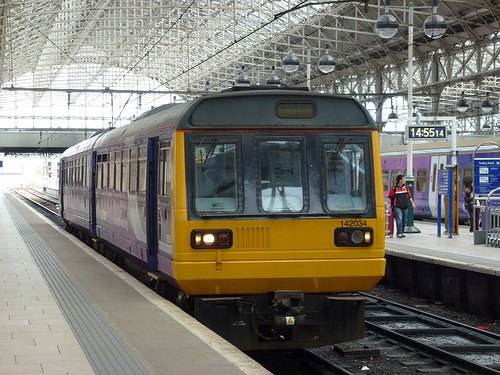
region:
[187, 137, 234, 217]
a window on a train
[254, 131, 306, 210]
a window on a train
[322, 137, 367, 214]
a window on a train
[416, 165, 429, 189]
a window on a train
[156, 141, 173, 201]
a window on a train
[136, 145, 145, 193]
a window on a train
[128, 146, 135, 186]
a window on a train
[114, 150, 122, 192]
a window on a train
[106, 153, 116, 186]
a window on a train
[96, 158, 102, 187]
a window on a train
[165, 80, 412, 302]
Back of yellow train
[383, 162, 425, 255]
Person walking on train platform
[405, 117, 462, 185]
Clock on a post on the train platform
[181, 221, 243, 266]
Lights on the back of the train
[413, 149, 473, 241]
Train on other side of platform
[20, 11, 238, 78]
Metal support rails in ceiling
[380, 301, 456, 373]
Train tracks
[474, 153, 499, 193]
Blue sign on platform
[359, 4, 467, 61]
Lights hanging from the ceiling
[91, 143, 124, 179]
Open windows on the train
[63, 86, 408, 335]
Commuter train on the tracks.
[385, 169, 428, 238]
Passenger on the platform.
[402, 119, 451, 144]
Digital clock on the platform.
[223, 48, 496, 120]
Lights at the train station.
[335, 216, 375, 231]
Identifying number on the train.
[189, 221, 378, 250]
Lights on the train.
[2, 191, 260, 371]
Platform made with cement and tile.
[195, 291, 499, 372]
Train tracks which carrying the trains.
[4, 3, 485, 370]
Train station with high roof.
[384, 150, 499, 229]
Purple, white and blue train.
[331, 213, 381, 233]
The train number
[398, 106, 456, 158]
A clock in military time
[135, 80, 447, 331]
A yellow and grey train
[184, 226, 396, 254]
Headlights on the train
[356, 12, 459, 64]
Glass domes over the lights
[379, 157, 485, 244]
Pedestrians standing on the sidewalk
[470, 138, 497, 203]
A blue and white sign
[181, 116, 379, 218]
Three windows for the windshield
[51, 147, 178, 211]
The windows for the passengers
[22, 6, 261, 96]
The metal bars that make the ceiling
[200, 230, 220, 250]
a head light of a train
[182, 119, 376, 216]
the windshield of the train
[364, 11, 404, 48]
an overhead light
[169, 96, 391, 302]
the yellow front of a train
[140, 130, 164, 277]
the door of a train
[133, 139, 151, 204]
a passenger window on the train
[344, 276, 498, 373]
a set of train tracks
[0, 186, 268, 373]
a train platform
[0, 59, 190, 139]
a bright gray sky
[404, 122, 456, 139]
the time display